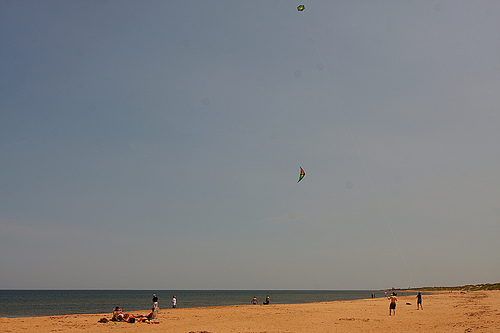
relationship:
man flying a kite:
[384, 288, 401, 316] [294, 161, 310, 185]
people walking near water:
[125, 289, 235, 329] [109, 276, 287, 308]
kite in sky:
[293, 162, 309, 189] [5, 6, 499, 284]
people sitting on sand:
[151, 293, 160, 310] [0, 315, 497, 329]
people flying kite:
[380, 285, 432, 323] [289, 162, 311, 185]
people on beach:
[380, 285, 432, 323] [200, 279, 487, 329]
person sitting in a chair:
[148, 302, 156, 317] [147, 306, 157, 321]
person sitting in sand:
[112, 305, 136, 323] [0, 289, 499, 331]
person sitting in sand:
[138, 296, 162, 323] [0, 289, 499, 331]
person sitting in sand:
[152, 293, 158, 307] [0, 289, 499, 331]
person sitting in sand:
[169, 294, 179, 307] [0, 289, 499, 331]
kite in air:
[297, 164, 309, 183] [49, 4, 444, 245]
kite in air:
[296, 4, 306, 11] [49, 4, 444, 245]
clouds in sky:
[0, 1, 499, 280] [176, 17, 498, 188]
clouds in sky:
[376, 55, 420, 95] [60, 32, 462, 187]